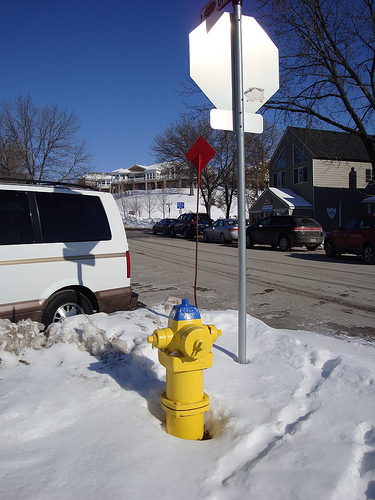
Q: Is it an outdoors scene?
A: Yes, it is outdoors.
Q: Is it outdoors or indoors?
A: It is outdoors.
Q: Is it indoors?
A: No, it is outdoors.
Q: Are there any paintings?
A: No, there are no paintings.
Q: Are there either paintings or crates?
A: No, there are no paintings or crates.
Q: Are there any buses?
A: No, there are no buses.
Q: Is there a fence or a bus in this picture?
A: No, there are no buses or fences.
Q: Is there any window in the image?
A: Yes, there is a window.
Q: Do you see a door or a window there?
A: Yes, there is a window.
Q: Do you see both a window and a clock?
A: No, there is a window but no clocks.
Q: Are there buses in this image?
A: No, there are no buses.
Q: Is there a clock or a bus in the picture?
A: No, there are no buses or clocks.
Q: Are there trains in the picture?
A: No, there are no trains.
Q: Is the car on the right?
A: Yes, the car is on the right of the image.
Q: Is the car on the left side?
A: No, the car is on the right of the image.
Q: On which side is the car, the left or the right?
A: The car is on the right of the image.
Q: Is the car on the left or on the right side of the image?
A: The car is on the right of the image.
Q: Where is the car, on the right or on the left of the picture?
A: The car is on the right of the image.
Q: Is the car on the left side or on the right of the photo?
A: The car is on the right of the image.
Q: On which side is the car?
A: The car is on the right of the image.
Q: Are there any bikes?
A: No, there are no bikes.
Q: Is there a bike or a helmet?
A: No, there are no bikes or helmets.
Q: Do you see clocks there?
A: No, there are no clocks.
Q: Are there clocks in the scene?
A: No, there are no clocks.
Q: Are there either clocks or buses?
A: No, there are no clocks or buses.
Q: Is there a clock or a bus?
A: No, there are no clocks or buses.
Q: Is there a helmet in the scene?
A: No, there are no helmets.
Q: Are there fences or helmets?
A: No, there are no helmets or fences.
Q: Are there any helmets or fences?
A: No, there are no helmets or fences.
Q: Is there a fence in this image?
A: No, there are no fences.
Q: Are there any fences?
A: No, there are no fences.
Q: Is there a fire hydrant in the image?
A: Yes, there is a fire hydrant.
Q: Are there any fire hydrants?
A: Yes, there is a fire hydrant.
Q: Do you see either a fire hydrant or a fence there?
A: Yes, there is a fire hydrant.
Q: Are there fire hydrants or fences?
A: Yes, there is a fire hydrant.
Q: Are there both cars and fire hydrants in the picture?
A: Yes, there are both a fire hydrant and a car.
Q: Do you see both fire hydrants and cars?
A: Yes, there are both a fire hydrant and a car.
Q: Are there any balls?
A: No, there are no balls.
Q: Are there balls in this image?
A: No, there are no balls.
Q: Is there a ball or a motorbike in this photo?
A: No, there are no balls or motorcycles.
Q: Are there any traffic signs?
A: Yes, there is a traffic sign.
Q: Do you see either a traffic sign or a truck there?
A: Yes, there is a traffic sign.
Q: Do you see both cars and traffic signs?
A: Yes, there are both a traffic sign and a car.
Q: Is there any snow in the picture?
A: Yes, there is snow.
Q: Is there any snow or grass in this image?
A: Yes, there is snow.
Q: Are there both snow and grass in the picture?
A: No, there is snow but no grass.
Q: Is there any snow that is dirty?
A: Yes, there is dirty snow.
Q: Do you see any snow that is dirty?
A: Yes, there is snow that is dirty.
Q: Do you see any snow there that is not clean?
A: Yes, there is dirty snow.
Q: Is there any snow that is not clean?
A: Yes, there is dirty snow.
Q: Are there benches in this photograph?
A: No, there are no benches.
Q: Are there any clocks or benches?
A: No, there are no benches or clocks.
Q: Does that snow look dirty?
A: Yes, the snow is dirty.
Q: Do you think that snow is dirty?
A: Yes, the snow is dirty.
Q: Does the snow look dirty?
A: Yes, the snow is dirty.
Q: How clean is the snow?
A: The snow is dirty.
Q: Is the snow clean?
A: No, the snow is dirty.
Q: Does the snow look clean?
A: No, the snow is dirty.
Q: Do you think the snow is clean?
A: No, the snow is dirty.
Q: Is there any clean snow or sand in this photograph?
A: No, there is snow but it is dirty.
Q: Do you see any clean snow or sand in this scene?
A: No, there is snow but it is dirty.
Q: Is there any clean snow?
A: No, there is snow but it is dirty.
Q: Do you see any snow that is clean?
A: No, there is snow but it is dirty.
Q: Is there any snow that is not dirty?
A: No, there is snow but it is dirty.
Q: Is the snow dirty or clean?
A: The snow is dirty.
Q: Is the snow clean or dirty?
A: The snow is dirty.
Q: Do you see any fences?
A: No, there are no fences.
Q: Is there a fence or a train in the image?
A: No, there are no fences or trains.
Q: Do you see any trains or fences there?
A: No, there are no fences or trains.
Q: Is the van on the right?
A: No, the van is on the left of the image.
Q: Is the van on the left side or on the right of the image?
A: The van is on the left of the image.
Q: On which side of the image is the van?
A: The van is on the left of the image.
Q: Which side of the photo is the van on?
A: The van is on the left of the image.